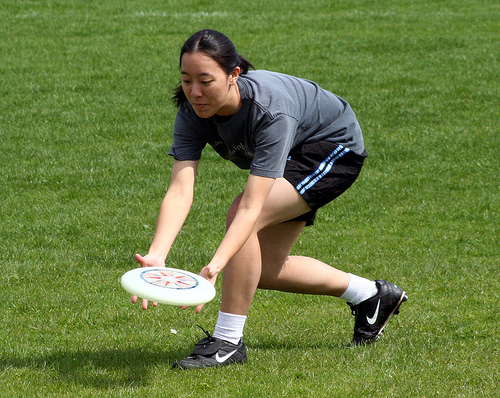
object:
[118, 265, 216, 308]
frisbee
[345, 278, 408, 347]
shoe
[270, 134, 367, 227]
shorts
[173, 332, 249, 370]
shoe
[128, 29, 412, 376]
woman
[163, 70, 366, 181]
shirt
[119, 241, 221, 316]
catching